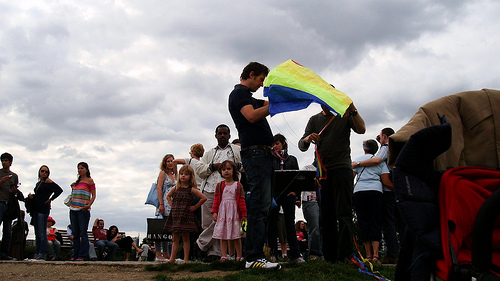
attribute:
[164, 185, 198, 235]
dress — little , brown  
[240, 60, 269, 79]
hair — short 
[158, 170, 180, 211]
dress — white, blue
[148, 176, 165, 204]
bag — blue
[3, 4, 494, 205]
clouds — white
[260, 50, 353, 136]
kite — yellow, blue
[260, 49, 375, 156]
flag — folded, blue, light green, yellow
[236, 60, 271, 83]
hair — dark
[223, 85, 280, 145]
shirt — black 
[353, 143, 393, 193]
shirts — light blue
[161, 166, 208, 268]
girl — little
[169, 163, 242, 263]
girls — young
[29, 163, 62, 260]
blackshirt woman — black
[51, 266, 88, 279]
sand — brown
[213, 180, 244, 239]
dress — pink 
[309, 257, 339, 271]
grass — green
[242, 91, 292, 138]
shirt — black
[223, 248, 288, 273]
shoes — white, yellow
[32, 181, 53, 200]
t-shirt — black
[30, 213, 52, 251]
pants — black